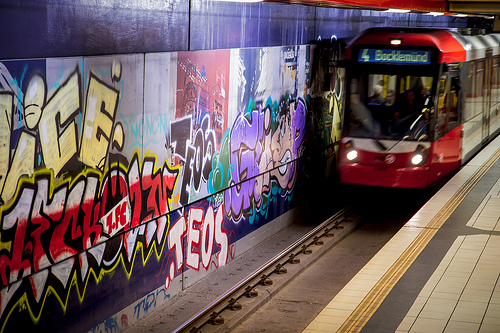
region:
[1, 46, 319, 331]
wall filled with graffiti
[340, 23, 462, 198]
front part of the train that is painted red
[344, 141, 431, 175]
train headlights are on and shining bright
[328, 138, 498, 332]
yellow line that people waiting for the train are supposed to stand behind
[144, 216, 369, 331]
train tracks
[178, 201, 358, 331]
steel rod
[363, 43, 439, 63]
blue sign with yellowish writing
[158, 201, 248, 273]
white writing with a red outline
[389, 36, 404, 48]
tiny light on the top of the train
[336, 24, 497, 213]
train pulling into the station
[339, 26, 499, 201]
a train cruising to the train platform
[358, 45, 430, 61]
the trains identification name and number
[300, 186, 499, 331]
the train station platform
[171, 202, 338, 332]
the trains steel rails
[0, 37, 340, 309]
a graffiti painted wall in the train station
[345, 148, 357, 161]
the trains front headlights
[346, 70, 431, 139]
the trains front windshield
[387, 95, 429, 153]
the front windshield wiper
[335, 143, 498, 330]
the yellow line is to inform passengers to stand behind the yellow line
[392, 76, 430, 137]
the silhouette of the train engineer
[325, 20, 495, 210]
a red moving train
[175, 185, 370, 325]
a train track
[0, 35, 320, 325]
a wall of painted graffiti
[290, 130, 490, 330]
a tiled train platform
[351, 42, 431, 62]
a train's destination sign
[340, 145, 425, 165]
a train's headlights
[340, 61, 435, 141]
a train's windshield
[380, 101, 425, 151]
a train's windshield wiper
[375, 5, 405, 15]
an overhead light bulb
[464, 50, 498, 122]
a train car's passenger windows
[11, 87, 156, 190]
Lice written on a wall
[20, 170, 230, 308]
writing on a wall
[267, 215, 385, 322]
Silver train track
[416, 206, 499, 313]
Tile by a train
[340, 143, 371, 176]
Light on a train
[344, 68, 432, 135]
Window on a train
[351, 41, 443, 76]
Sign on a train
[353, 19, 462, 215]
Red and white train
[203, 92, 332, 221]
Purple and orange writing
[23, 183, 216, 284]
Red and white writing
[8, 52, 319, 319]
There is graffiti on the wall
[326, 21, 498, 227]
The train is coming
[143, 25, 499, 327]
The train is on the track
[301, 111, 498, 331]
There is a yellow border by the train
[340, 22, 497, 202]
The train is red and silver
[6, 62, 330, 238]
The graffiti is colorful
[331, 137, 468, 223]
The train has headlights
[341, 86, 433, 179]
The train has wiper blades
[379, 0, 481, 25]
There are lights above the train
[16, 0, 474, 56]
Part of the wall is blue